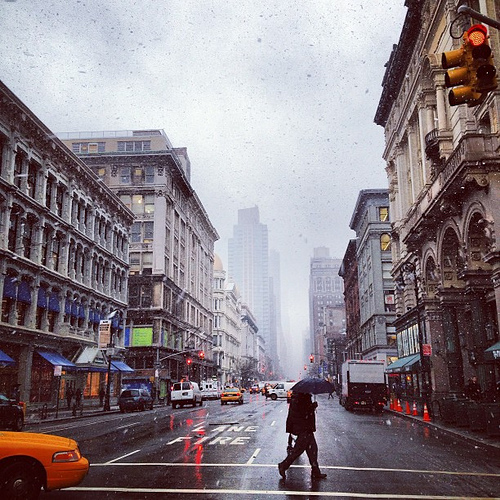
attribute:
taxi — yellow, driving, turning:
[0, 427, 90, 499]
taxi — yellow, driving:
[220, 385, 243, 405]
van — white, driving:
[169, 380, 203, 407]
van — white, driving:
[263, 380, 299, 400]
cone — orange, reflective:
[421, 403, 431, 423]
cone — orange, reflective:
[410, 401, 420, 417]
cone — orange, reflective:
[404, 399, 412, 413]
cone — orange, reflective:
[395, 397, 403, 413]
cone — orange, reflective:
[388, 395, 395, 411]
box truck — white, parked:
[337, 358, 390, 414]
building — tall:
[375, 3, 498, 443]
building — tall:
[56, 127, 218, 405]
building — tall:
[0, 79, 137, 428]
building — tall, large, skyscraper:
[225, 204, 274, 383]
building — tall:
[308, 245, 347, 385]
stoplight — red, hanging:
[458, 23, 498, 93]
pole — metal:
[456, 4, 500, 32]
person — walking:
[276, 385, 327, 482]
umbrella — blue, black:
[291, 375, 337, 397]